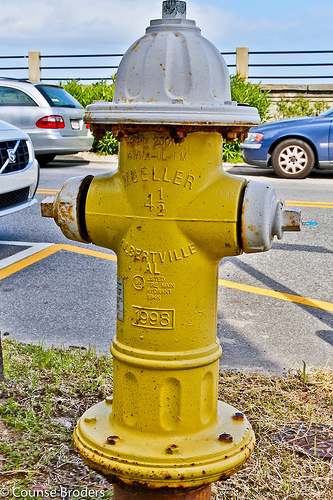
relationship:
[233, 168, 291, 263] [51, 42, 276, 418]
outlet attached to fire hydrant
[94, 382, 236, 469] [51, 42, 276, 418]
bolts attached to fire hydrant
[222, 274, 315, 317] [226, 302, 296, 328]
lines on road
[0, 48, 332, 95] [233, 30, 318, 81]
railing attached to wall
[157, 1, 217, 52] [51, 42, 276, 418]
cap of fire hydrant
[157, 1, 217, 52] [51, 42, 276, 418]
cap on fire hydrant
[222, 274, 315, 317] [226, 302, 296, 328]
lines painted on road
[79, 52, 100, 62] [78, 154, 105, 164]
railing on side of sidewalk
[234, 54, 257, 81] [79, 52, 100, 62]
post attached to railing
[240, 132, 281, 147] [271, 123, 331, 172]
headlight in front of car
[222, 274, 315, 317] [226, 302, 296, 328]
lines in road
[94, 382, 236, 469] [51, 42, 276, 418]
bolts under fire hydrant